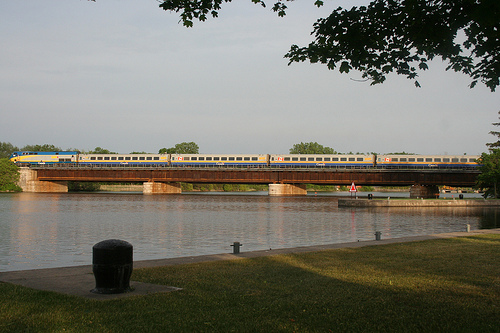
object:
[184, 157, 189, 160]
passenger window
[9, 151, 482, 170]
passenger train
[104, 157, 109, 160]
train window